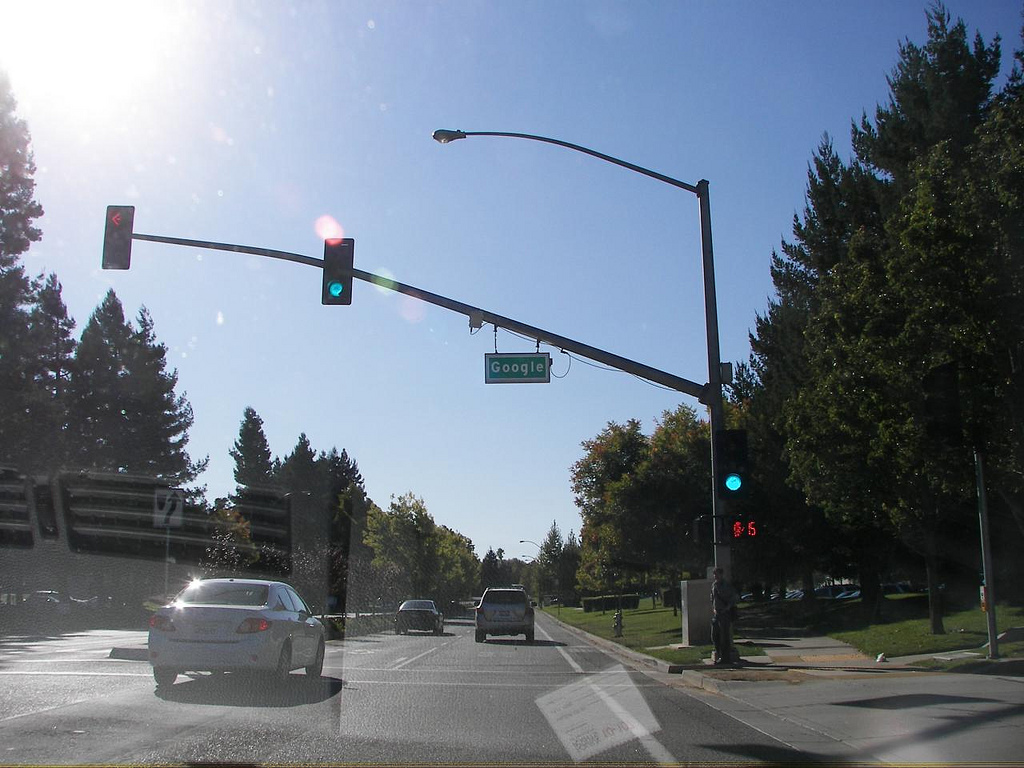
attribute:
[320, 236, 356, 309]
signal — electric 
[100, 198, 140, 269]
signal — electric 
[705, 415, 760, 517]
traffic signal — electric 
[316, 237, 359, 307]
traffic signal — electric 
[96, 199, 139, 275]
traffic signal — electric 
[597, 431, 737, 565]
leaves — green 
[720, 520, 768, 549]
signal — do not walk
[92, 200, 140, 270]
signal — electric 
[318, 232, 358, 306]
signal — electric 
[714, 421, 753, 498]
signal — electric 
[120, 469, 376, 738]
car — white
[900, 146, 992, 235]
leaves — green 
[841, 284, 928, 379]
green leaves — green 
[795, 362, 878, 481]
green leaves — green 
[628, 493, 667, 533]
green leaves — green 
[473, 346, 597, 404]
street sign — name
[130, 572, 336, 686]
car — white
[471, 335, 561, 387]
sign — Green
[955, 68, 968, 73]
leaf — green 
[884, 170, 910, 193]
leaf — green 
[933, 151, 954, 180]
leaf — green 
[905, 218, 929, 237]
leaf — green 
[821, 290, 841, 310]
leaf — green 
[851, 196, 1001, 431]
leaves — green 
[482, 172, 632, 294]
sky — blue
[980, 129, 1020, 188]
leaves — green 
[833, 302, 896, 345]
leaves — green 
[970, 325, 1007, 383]
leaves — green 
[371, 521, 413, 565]
leaves — green 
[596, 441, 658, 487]
leaves — green 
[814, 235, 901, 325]
leaves — green